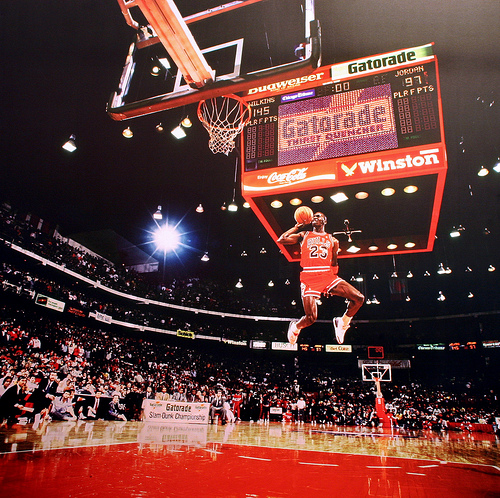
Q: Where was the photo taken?
A: It was taken at the stadium.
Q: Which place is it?
A: It is a stadium.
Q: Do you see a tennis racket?
A: No, there are no rackets.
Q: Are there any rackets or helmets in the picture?
A: No, there are no rackets or helmets.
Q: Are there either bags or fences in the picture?
A: No, there are no fences or bags.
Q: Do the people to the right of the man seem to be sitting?
A: Yes, the people are sitting.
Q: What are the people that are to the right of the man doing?
A: The people are sitting.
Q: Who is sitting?
A: The people are sitting.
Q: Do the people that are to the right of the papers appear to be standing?
A: No, the people are sitting.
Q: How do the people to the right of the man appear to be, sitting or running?
A: The people are sitting.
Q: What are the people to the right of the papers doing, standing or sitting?
A: The people are sitting.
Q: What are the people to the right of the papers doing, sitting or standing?
A: The people are sitting.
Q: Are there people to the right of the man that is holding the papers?
A: Yes, there are people to the right of the man.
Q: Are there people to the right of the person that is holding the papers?
A: Yes, there are people to the right of the man.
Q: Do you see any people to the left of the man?
A: No, the people are to the right of the man.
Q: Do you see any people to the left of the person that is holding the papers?
A: No, the people are to the right of the man.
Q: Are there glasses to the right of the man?
A: No, there are people to the right of the man.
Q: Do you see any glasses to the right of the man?
A: No, there are people to the right of the man.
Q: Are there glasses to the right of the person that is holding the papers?
A: No, there are people to the right of the man.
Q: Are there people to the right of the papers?
A: Yes, there are people to the right of the papers.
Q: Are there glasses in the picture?
A: No, there are no glasses.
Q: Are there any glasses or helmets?
A: No, there are no glasses or helmets.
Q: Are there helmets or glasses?
A: No, there are no glasses or helmets.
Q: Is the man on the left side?
A: Yes, the man is on the left of the image.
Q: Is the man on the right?
A: No, the man is on the left of the image.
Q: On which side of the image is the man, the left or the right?
A: The man is on the left of the image.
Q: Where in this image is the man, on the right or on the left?
A: The man is on the left of the image.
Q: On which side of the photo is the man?
A: The man is on the left of the image.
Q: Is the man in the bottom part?
A: Yes, the man is in the bottom of the image.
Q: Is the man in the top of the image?
A: No, the man is in the bottom of the image.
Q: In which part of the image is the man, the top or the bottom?
A: The man is in the bottom of the image.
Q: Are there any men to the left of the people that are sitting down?
A: Yes, there is a man to the left of the people.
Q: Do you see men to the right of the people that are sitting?
A: No, the man is to the left of the people.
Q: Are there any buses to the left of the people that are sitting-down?
A: No, there is a man to the left of the people.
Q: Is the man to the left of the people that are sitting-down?
A: Yes, the man is to the left of the people.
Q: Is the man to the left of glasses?
A: No, the man is to the left of the people.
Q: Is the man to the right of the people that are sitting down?
A: No, the man is to the left of the people.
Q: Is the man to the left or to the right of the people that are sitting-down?
A: The man is to the left of the people.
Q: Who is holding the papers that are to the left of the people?
A: The man is holding the papers.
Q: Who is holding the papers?
A: The man is holding the papers.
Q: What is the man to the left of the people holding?
A: The man is holding the papers.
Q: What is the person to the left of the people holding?
A: The man is holding the papers.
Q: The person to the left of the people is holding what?
A: The man is holding the papers.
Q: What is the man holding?
A: The man is holding the papers.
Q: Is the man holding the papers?
A: Yes, the man is holding the papers.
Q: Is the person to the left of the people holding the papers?
A: Yes, the man is holding the papers.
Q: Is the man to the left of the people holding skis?
A: No, the man is holding the papers.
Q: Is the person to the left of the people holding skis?
A: No, the man is holding the papers.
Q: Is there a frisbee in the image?
A: No, there are no frisbees.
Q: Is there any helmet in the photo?
A: No, there are no helmets.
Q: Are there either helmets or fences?
A: No, there are no helmets or fences.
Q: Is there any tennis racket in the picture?
A: No, there are no rackets.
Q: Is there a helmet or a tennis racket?
A: No, there are no rackets or helmets.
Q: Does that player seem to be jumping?
A: Yes, the player is jumping.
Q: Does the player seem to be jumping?
A: Yes, the player is jumping.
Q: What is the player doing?
A: The player is jumping.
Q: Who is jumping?
A: The player is jumping.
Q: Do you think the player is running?
A: No, the player is jumping.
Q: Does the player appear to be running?
A: No, the player is jumping.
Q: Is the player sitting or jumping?
A: The player is jumping.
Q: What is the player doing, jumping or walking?
A: The player is jumping.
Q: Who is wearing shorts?
A: The player is wearing shorts.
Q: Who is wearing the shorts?
A: The player is wearing shorts.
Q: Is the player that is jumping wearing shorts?
A: Yes, the player is wearing shorts.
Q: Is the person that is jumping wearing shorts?
A: Yes, the player is wearing shorts.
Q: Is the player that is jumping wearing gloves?
A: No, the player is wearing shorts.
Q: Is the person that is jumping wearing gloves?
A: No, the player is wearing shorts.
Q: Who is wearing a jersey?
A: The player is wearing a jersey.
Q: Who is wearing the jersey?
A: The player is wearing a jersey.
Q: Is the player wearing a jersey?
A: Yes, the player is wearing a jersey.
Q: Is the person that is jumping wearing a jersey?
A: Yes, the player is wearing a jersey.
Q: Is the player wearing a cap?
A: No, the player is wearing a jersey.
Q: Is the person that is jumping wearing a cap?
A: No, the player is wearing a jersey.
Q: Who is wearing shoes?
A: The player is wearing shoes.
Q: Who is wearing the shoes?
A: The player is wearing shoes.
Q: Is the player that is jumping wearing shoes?
A: Yes, the player is wearing shoes.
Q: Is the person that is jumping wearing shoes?
A: Yes, the player is wearing shoes.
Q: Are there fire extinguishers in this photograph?
A: No, there are no fire extinguishers.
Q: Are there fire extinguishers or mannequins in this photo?
A: No, there are no fire extinguishers or mannequins.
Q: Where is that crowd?
A: The crowd is in the stadium.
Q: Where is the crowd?
A: The crowd is in the stadium.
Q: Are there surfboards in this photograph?
A: No, there are no surfboards.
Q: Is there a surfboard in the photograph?
A: No, there are no surfboards.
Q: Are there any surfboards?
A: No, there are no surfboards.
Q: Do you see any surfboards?
A: No, there are no surfboards.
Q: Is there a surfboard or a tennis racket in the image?
A: No, there are no surfboards or rackets.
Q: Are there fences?
A: No, there are no fences.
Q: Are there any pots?
A: No, there are no pots.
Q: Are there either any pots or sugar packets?
A: No, there are no pots or sugar packets.